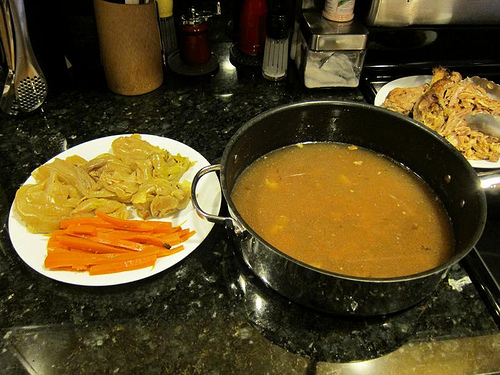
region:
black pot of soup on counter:
[195, 93, 491, 328]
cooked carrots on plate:
[38, 208, 195, 278]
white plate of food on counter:
[5, 126, 225, 302]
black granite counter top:
[30, 303, 487, 374]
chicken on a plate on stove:
[365, 57, 497, 179]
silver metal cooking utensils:
[0, 0, 59, 125]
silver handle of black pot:
[188, 161, 230, 233]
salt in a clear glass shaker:
[256, 14, 306, 94]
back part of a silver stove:
[359, 0, 498, 75]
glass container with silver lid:
[290, 10, 372, 97]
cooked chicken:
[416, 83, 456, 115]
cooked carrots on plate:
[70, 230, 136, 255]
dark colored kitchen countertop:
[40, 301, 245, 342]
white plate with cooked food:
[5, 127, 205, 282]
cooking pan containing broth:
[217, 105, 467, 315]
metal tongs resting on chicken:
[460, 71, 496, 131]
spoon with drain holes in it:
[6, 0, 51, 115]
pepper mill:
[175, 0, 227, 80]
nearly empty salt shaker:
[255, 6, 290, 81]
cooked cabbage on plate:
[55, 155, 165, 200]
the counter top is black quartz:
[11, 37, 498, 373]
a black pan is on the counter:
[190, 97, 487, 319]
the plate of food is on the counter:
[8, 130, 222, 289]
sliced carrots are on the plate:
[43, 210, 197, 277]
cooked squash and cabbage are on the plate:
[16, 137, 193, 223]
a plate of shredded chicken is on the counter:
[372, 73, 499, 165]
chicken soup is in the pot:
[240, 140, 457, 282]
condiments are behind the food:
[6, 4, 497, 107]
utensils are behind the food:
[2, 0, 354, 101]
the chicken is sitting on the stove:
[360, 0, 497, 328]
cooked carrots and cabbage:
[14, 121, 205, 307]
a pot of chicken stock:
[207, 67, 497, 288]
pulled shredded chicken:
[387, 45, 492, 164]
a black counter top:
[80, 310, 250, 362]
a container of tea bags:
[297, 6, 369, 98]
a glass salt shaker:
[255, 15, 311, 96]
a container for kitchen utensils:
[86, 5, 179, 104]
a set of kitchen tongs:
[470, 64, 498, 143]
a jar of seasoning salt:
[313, 2, 375, 22]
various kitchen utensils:
[3, 17, 80, 132]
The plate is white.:
[2, 143, 212, 289]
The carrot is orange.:
[40, 216, 183, 290]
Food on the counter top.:
[26, 135, 476, 317]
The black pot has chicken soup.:
[216, 131, 481, 326]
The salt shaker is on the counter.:
[253, 16, 307, 90]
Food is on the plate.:
[2, 142, 261, 279]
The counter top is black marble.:
[46, 310, 356, 373]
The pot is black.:
[226, 86, 495, 313]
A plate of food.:
[407, 54, 497, 172]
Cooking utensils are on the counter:
[6, 9, 75, 115]